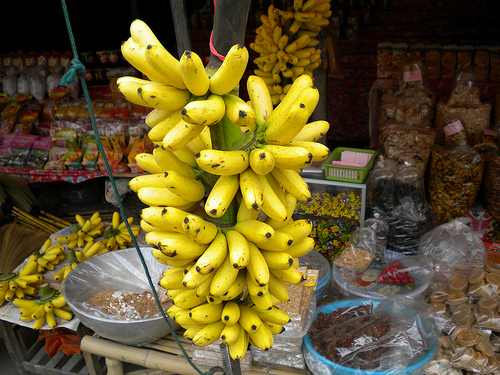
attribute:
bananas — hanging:
[59, 230, 124, 253]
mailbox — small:
[332, 147, 375, 177]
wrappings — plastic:
[342, 249, 429, 293]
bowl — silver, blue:
[103, 322, 150, 344]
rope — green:
[55, 8, 98, 117]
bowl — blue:
[311, 354, 332, 372]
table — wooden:
[3, 308, 11, 323]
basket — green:
[324, 165, 367, 182]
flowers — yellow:
[316, 191, 360, 222]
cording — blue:
[126, 228, 152, 285]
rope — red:
[206, 41, 228, 66]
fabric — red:
[34, 171, 51, 180]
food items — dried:
[394, 45, 491, 63]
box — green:
[338, 147, 371, 164]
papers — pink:
[338, 151, 370, 165]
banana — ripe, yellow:
[168, 48, 214, 98]